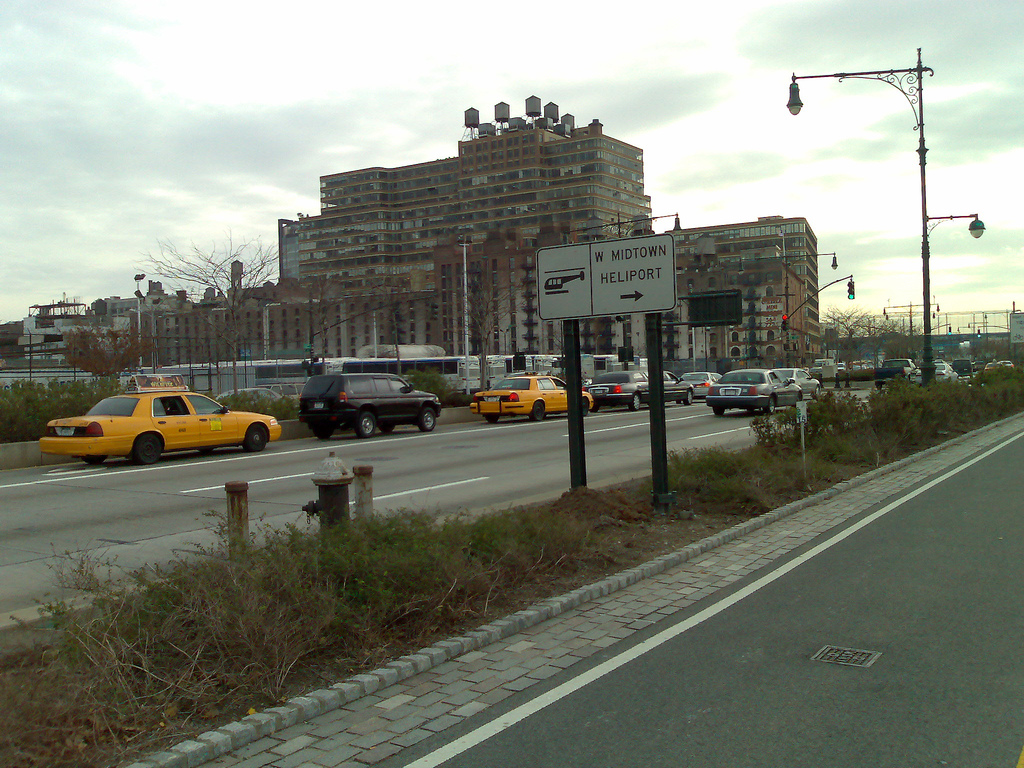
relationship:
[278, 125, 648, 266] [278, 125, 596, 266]
building on side of wall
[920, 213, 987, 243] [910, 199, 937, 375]
light on pole